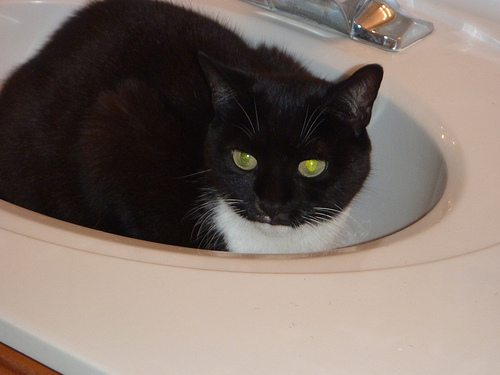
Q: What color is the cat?
A: Black and white.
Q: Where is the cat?
A: In the bathroom.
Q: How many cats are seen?
A: One.